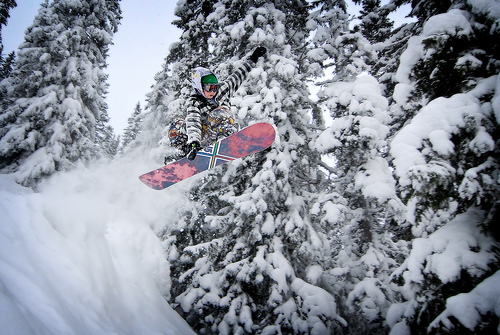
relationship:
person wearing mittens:
[159, 36, 273, 173] [239, 40, 282, 66]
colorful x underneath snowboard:
[197, 139, 235, 169] [138, 122, 277, 191]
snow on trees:
[0, 0, 500, 335] [0, 2, 497, 333]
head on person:
[192, 66, 221, 100] [189, 60, 221, 104]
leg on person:
[168, 110, 183, 152] [178, 104, 208, 152]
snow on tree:
[0, 0, 500, 335] [152, 0, 499, 331]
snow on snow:
[0, 0, 122, 185] [0, 0, 500, 335]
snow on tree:
[0, 0, 500, 335] [0, 1, 124, 183]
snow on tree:
[0, 0, 500, 335] [172, 10, 399, 332]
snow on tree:
[0, 0, 500, 335] [168, 50, 398, 331]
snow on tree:
[0, 0, 500, 335] [223, 161, 480, 323]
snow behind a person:
[0, 0, 500, 335] [167, 51, 262, 159]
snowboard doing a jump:
[138, 123, 276, 191] [127, 108, 307, 208]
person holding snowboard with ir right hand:
[164, 46, 266, 161] [175, 97, 207, 184]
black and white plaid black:
[184, 49, 254, 154] [180, 55, 257, 148]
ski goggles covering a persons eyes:
[201, 78, 235, 120] [210, 99, 247, 147]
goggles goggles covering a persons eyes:
[200, 78, 225, 93] [210, 99, 247, 147]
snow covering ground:
[21, 258, 420, 328] [4, 178, 498, 335]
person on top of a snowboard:
[164, 46, 266, 161] [138, 122, 277, 191]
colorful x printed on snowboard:
[197, 139, 235, 169] [135, 117, 277, 195]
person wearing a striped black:
[164, 46, 266, 161] [180, 55, 257, 148]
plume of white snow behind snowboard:
[70, 172, 139, 230] [129, 121, 294, 194]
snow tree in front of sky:
[0, 0, 500, 335] [123, 22, 160, 64]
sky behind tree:
[123, 7, 165, 61] [71, 49, 118, 113]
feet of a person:
[186, 135, 215, 172] [176, 98, 234, 186]